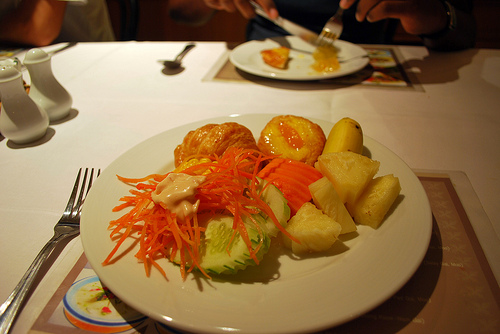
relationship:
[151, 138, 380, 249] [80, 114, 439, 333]
food on plate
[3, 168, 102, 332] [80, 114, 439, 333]
fork next to plate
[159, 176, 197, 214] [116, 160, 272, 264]
dressing on carrots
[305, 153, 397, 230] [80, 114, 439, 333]
pineapple on plate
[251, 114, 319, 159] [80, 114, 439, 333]
scallop on plate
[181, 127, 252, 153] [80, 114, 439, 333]
croissant on plate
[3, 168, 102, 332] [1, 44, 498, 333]
fork on table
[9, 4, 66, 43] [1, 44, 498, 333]
elbow on table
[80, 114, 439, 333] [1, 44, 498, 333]
plate on table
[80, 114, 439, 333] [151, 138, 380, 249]
plate of food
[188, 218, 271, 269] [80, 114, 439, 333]
cucumber slices on plate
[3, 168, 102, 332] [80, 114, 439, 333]
fork on left side of plate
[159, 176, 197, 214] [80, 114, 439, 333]
dressing on plate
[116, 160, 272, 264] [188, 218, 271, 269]
carrots next to cucumber slices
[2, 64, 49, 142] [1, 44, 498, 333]
salt shaker on table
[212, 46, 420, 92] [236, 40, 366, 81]
paper place mat under plate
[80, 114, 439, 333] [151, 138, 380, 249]
plate with food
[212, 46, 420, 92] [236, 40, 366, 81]
paper place mat underneath plate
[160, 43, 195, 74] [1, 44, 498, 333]
spoon on table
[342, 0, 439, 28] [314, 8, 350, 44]
hand holding fork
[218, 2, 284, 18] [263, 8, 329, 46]
hand holding knife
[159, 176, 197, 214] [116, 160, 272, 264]
sauce on carrots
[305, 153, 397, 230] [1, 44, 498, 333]
pineapple on table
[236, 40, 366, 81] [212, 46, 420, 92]
plate sitting on paper place mat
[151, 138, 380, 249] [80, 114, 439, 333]
meal on plate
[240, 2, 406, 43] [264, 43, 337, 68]
man cutting food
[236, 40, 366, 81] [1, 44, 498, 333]
plate on table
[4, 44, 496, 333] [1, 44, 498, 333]
tablecloth on table